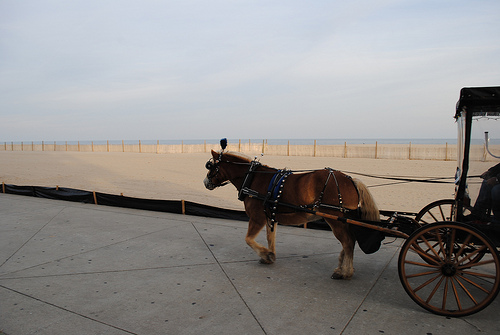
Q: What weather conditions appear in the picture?
A: It is cloudy.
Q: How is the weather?
A: It is cloudy.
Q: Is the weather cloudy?
A: Yes, it is cloudy.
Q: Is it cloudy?
A: Yes, it is cloudy.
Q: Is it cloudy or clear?
A: It is cloudy.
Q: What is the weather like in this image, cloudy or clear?
A: It is cloudy.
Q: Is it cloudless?
A: No, it is cloudy.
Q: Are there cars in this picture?
A: No, there are no cars.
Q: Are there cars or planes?
A: No, there are no cars or planes.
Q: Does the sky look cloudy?
A: Yes, the sky is cloudy.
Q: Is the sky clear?
A: No, the sky is cloudy.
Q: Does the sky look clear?
A: No, the sky is cloudy.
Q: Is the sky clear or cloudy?
A: The sky is cloudy.